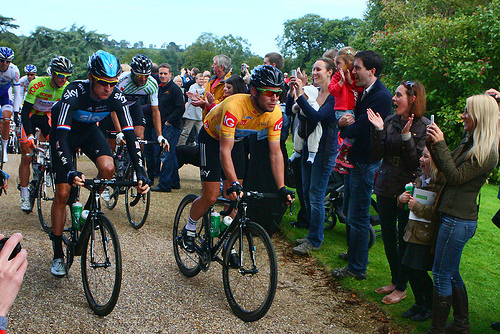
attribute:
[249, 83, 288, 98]
sunglasses — green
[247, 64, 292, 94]
helmet — cycling helmet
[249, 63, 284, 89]
helmet — black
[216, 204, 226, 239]
bottle — green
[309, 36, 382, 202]
girl — young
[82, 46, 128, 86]
helmet — teal, black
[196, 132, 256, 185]
shorts — black, white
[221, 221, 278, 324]
wheel — black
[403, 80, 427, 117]
hair — light brown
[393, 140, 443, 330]
girl — little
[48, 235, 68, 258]
sock — black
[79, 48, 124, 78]
helmet — blue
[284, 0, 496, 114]
trees — green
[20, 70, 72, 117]
top — lime green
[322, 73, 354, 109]
shirt — red